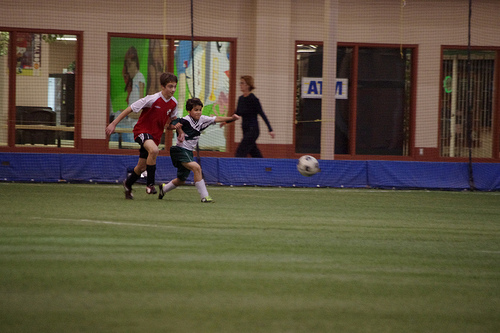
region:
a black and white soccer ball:
[293, 154, 323, 176]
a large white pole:
[315, 0, 344, 161]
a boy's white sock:
[195, 178, 210, 198]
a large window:
[12, 27, 79, 144]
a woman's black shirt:
[231, 93, 273, 135]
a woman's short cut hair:
[237, 70, 257, 93]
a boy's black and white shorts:
[134, 132, 157, 159]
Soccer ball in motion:
[289, 150, 324, 182]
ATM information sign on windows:
[300, 75, 350, 102]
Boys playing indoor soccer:
[95, 70, 241, 205]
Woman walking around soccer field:
[222, 68, 277, 161]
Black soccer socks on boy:
[119, 161, 164, 189]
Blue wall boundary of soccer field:
[4, 147, 499, 194]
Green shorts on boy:
[163, 145, 202, 165]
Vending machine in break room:
[45, 74, 75, 138]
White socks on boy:
[158, 178, 210, 200]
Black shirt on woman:
[227, 93, 274, 136]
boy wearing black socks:
[129, 173, 137, 184]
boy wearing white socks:
[195, 181, 207, 196]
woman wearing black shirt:
[243, 103, 256, 120]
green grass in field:
[248, 239, 310, 282]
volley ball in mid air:
[292, 147, 324, 182]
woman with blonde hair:
[246, 72, 254, 86]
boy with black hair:
[189, 98, 196, 107]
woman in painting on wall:
[116, 44, 146, 101]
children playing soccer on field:
[105, 63, 355, 254]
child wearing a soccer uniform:
[173, 95, 240, 193]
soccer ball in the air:
[285, 152, 337, 182]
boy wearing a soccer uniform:
[160, 85, 237, 202]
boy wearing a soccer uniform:
[102, 62, 183, 206]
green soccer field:
[183, 226, 243, 293]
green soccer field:
[35, 246, 126, 287]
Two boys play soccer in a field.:
[93, 57, 243, 222]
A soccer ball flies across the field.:
[288, 154, 327, 176]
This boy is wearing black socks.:
[116, 166, 157, 201]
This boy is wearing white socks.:
[162, 177, 224, 209]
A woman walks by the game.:
[222, 71, 277, 158]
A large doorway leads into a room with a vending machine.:
[3, 24, 87, 151]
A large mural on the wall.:
[107, 29, 240, 146]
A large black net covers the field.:
[408, 4, 469, 159]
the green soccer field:
[220, 235, 297, 299]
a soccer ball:
[296, 154, 317, 174]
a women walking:
[231, 71, 273, 148]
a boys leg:
[143, 136, 160, 164]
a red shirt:
[144, 111, 162, 130]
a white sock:
[196, 175, 211, 197]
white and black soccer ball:
[295, 151, 322, 174]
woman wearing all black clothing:
[218, 73, 274, 154]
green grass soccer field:
[0, 181, 498, 331]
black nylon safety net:
[0, 0, 497, 191]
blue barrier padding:
[1, 151, 498, 189]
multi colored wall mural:
[110, 35, 232, 150]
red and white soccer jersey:
[129, 92, 179, 144]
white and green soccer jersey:
[167, 111, 217, 151]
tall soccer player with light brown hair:
[104, 69, 180, 201]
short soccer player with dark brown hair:
[157, 95, 240, 205]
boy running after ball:
[156, 89, 246, 206]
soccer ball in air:
[296, 149, 318, 178]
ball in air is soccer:
[289, 148, 318, 176]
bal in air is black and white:
[294, 149, 322, 180]